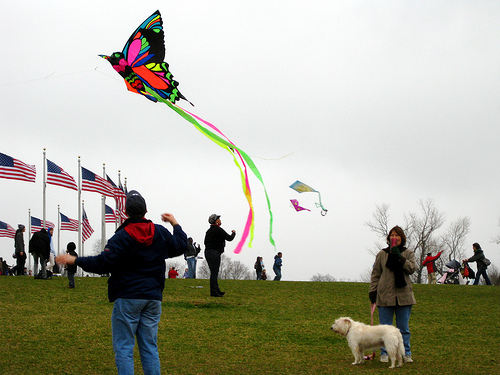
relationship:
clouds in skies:
[6, 20, 498, 276] [326, 3, 443, 183]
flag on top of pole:
[45, 157, 75, 191] [76, 155, 82, 255]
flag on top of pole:
[59, 210, 79, 232] [41, 148, 46, 225]